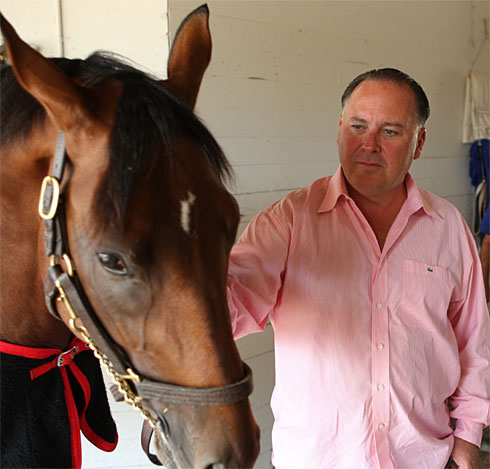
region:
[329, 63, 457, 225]
head of a person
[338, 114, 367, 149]
eye of a person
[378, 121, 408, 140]
eye of a person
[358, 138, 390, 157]
nose of a person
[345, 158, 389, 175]
mouth of a person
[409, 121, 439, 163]
ear of a person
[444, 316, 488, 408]
arm of a person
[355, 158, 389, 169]
lips of a person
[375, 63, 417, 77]
hair of a person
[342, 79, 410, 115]
forehead of a person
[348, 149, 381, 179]
mouth of a person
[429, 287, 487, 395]
arm of a person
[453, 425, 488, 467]
hand of a person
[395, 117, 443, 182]
ear of a person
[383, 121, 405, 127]
eyebrow of a person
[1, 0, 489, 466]
man in a pink shirt petting a horse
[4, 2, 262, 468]
brown horse with a white spot on its head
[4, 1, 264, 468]
brown horse with a bridle over its face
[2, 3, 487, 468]
man in a button down shirt looking at a horse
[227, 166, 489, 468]
pink button down shirt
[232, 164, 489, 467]
pink shirt with a chest pocket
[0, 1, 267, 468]
a horse with brown hair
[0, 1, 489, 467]
man and a horse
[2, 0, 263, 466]
horse wearing a black and red wrap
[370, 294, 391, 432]
line of white buttons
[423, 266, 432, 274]
Logo on shirt pocket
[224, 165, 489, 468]
Pink long sleeve shirt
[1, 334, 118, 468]
Red and black horse blanket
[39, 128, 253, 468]
Brown and gold horse bridle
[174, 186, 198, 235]
White marking on head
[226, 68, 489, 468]
Man holding onto a horse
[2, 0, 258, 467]
Brown horse in a stable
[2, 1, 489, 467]
White walls in the background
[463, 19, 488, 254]
Items hanging on the wall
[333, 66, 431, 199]
The man is not smiling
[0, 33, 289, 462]
this is a head of a horse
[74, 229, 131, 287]
this is an eye of a horse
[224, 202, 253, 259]
this is an eye of a horse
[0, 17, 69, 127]
this is an ear of a horse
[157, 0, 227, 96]
this is an ear of a horse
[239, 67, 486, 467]
this is a person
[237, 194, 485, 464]
this is a pink shirt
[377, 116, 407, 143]
an eye of a person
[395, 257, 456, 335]
this is shirt poket